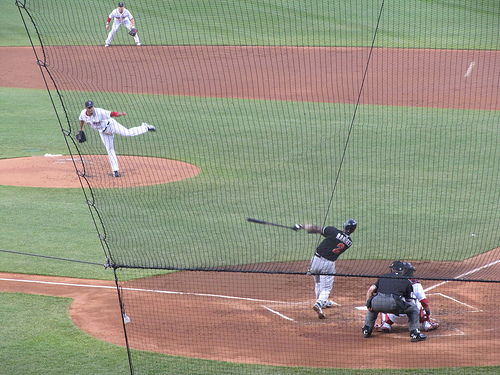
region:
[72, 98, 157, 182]
a pitcher throwing a ball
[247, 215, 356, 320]
a baseball player swinging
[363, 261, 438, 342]
a catcher and an umpire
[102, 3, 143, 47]
a baseball player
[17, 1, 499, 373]
netting for a baseball field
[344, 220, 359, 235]
back of a baseball helmet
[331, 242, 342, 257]
a red number two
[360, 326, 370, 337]
the back of a shoe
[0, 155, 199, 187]
the pitchers mound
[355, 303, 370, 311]
section of a home base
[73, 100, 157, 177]
pitcher releasing the baseball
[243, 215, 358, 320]
batters swings at ball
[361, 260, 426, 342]
umpire watches thrown ball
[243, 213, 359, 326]
batter in batter's box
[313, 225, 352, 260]
batter is jersey #2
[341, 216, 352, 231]
batter wearing batter's helmet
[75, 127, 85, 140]
pitcher wearing baseball glove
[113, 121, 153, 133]
pitcher's left leg is up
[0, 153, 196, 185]
pitcher's mound is dirt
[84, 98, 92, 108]
pitcher wearing a cap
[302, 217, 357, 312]
Batter is wearing black helmet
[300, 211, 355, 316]
Batter is wearing black jersey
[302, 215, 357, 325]
Batter is wearing gray pants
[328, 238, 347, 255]
Red number 2 printed on black jersey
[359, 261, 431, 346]
Umpire crouching behind catcher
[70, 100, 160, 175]
Pitcher has lifted leg up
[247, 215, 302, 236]
Long black wooden bat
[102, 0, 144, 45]
Player holding black baseball glove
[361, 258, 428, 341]
Umpire wearing black hat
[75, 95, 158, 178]
Pitcher wearing blue hat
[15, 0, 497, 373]
large black net behind umpire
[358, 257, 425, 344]
umpire is crouching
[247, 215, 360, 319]
batter is swinging a bat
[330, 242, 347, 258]
red number on black jersey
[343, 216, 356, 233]
black batter's helmet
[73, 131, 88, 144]
pitcher holding black glove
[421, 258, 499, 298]
white first base line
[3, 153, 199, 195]
pitchers mound is round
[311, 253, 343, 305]
batter wearing white pants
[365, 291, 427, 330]
gray pants on umpire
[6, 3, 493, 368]
a professional baseball game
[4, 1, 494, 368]
four baseball players and an umpire on the baseball field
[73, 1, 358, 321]
three professional baseball players standing on the field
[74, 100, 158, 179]
the baseball pitcher of a professional team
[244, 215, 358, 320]
a baseball batter in black and white uniform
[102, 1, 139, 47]
an outfield baseball player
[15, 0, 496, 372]
a blue net in the baseball stadium stand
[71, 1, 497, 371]
a view of the baseball game behind a net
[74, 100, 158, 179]
a pitcher in a throwing position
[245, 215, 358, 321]
a batter swinging a bat